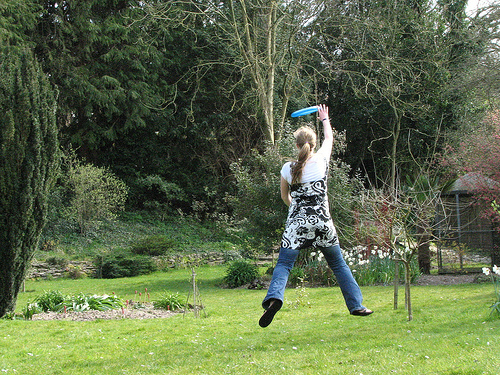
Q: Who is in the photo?
A: A girl.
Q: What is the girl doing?
A: Trying to catch frisbee.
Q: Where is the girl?
A: Back yard.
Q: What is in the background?
A: Trees.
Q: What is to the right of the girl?
A: Small bare trees.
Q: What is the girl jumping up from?
A: Grass.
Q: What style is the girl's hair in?
A: Ponytail.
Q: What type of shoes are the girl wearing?
A: Sandals.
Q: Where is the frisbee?
A: In the air.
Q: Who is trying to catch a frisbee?
A: Girl wearing black and white top.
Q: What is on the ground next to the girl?
A: Rock ledge with bushes.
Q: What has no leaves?
A: Tree branches.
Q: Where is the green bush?
A: By the garden.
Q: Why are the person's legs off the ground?
A: Jumping for frisbee.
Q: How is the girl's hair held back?
A: In ponytail.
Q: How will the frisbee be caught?
A: By the girl's right hand.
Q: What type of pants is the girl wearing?
A: Jeans.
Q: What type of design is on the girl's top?
A: Black and white abstract.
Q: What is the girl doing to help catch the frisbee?
A: Jumping.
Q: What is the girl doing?
A: Catching a frisbee.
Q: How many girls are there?
A: One.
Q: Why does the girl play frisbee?
A: It is fun.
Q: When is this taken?
A: During the daytime.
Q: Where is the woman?
A: In the air.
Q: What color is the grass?
A: Green.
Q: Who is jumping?
A: The woman.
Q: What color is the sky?
A: Blue.